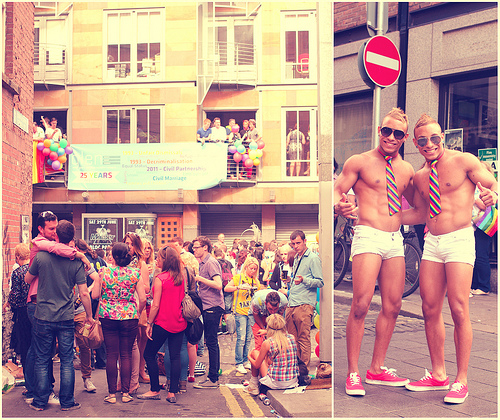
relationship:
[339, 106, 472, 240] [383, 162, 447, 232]
men wearing neckties